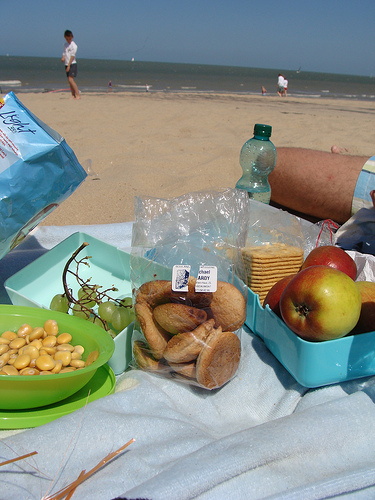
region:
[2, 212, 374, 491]
a blanket covered with assorted foods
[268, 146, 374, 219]
the man's leg sitting on the blanket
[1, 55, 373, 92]
the ocean next to the beach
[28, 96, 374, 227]
the beach next to the ocean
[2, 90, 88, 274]
a bag of potato chips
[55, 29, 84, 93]
a person standing on the beach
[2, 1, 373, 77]
the blue sky above the oceans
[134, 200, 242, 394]
a bag filled with some cookies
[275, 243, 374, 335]
some apples sitting in a box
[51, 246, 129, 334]
some green grapes sitting on the vine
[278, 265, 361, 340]
A big apple on a plate.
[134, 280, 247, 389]
Some kind of bread in a bag.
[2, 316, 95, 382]
A bowl full of nuts.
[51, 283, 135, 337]
A try full of grapes.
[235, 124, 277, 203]
A water bottle sitting on the ground.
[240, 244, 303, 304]
A stack of crackers on the blanket.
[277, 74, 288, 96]
Two people walking on the beach.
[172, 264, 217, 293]
A ripped label on a bag.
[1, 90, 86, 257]
A potato chip bag.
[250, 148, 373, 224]
Someones knee on the ground.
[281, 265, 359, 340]
a large red and green apple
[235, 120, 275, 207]
a bottle of water with a green lid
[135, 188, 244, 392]
a clear plastic bag full of cookies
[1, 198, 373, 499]
food sitting on a light blue beach blanket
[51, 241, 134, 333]
green grapes in a light blue container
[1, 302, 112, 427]
a large green bowl full of beans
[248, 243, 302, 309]
a stack of crispy crackers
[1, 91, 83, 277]
an opened bag of light potato chips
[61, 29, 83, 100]
a person in a white shirt standing on the beach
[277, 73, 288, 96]
two people walking on the beach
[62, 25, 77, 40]
head of a person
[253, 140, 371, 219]
leg of a person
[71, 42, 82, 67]
arm of a person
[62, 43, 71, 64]
arm of a person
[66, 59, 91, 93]
leg of a person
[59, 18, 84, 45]
a head of a person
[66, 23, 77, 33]
hair of a person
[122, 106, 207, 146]
a sand on a beach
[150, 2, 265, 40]
a sky with no clouds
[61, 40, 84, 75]
the body of a person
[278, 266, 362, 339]
red and green colored apple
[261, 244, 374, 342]
four green and red colored apples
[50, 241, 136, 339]
green grapes on a brown stem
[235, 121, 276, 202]
closed blue plastic bottle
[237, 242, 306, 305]
stack of crispy crackers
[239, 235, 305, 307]
pack containing many crackers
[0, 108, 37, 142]
blue print reading Light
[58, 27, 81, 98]
young boy wearing a white shirt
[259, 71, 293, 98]
two adults and child walking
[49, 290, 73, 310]
green grape hanging from a brown stem